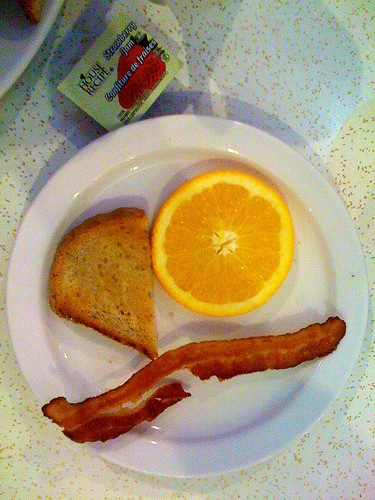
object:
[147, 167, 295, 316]
orange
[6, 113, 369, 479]
plate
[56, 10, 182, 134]
jam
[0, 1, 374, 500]
table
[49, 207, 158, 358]
toast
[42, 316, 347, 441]
bacon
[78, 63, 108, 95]
words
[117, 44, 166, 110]
strawberry